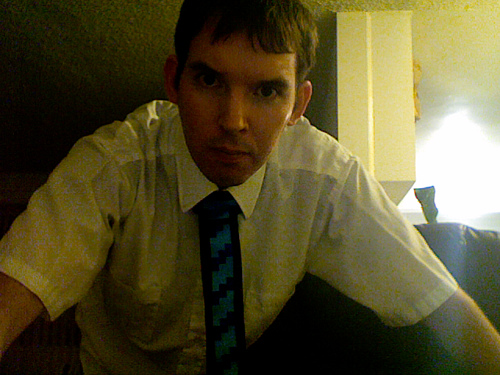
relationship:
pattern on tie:
[208, 223, 240, 374] [181, 187, 247, 373]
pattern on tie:
[208, 223, 240, 374] [188, 184, 255, 372]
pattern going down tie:
[202, 222, 241, 363] [192, 191, 252, 371]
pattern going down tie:
[208, 223, 240, 374] [164, 189, 244, 366]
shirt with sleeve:
[9, 99, 459, 357] [309, 158, 459, 333]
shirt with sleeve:
[9, 99, 459, 357] [4, 131, 121, 321]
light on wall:
[395, 105, 484, 224] [385, 13, 483, 218]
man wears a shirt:
[0, 0, 500, 375] [254, 174, 394, 305]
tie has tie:
[192, 183, 249, 352] [192, 189, 247, 375]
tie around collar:
[192, 189, 247, 375] [175, 160, 273, 229]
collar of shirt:
[175, 160, 273, 229] [289, 169, 425, 317]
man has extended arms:
[118, 11, 352, 346] [20, 188, 483, 368]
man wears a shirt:
[0, 0, 500, 375] [73, 156, 199, 351]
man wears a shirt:
[0, 0, 500, 375] [37, 140, 229, 363]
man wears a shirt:
[0, 0, 500, 375] [0, 99, 461, 375]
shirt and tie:
[0, 99, 461, 375] [188, 204, 270, 354]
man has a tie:
[0, 0, 500, 375] [202, 194, 252, 373]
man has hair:
[0, 0, 500, 375] [196, 0, 286, 49]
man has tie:
[0, 0, 500, 375] [192, 200, 267, 365]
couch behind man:
[336, 208, 490, 325] [0, 0, 500, 375]